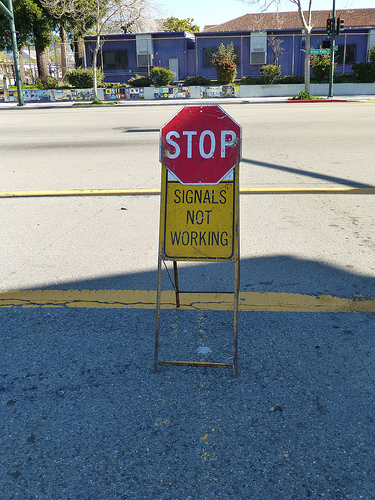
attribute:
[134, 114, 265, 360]
sign — red, yellow, black, on street, octagonal, white, stop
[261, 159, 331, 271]
street — gray, cracked, in middle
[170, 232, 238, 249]
letters — black, on sign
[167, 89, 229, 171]
sign — red, white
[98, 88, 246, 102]
wall — colorful, cement, covered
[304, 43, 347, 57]
street sign — green, near tree, white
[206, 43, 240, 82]
bush — green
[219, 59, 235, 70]
flowers — on bush, maroon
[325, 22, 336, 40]
traffic signal — facing straight, facing right, green, multi colored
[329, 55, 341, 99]
traffic pole — silver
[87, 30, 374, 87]
house — blue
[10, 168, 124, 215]
line — on street, yellow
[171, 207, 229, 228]
word — not, signals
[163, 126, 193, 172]
letter — s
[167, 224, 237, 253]
word — working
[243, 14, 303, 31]
roof — brown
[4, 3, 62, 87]
tree — green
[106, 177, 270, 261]
sign — yellow, black, signal not working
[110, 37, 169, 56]
fence — tall, metal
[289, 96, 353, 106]
curb — red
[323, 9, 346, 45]
light — traffic